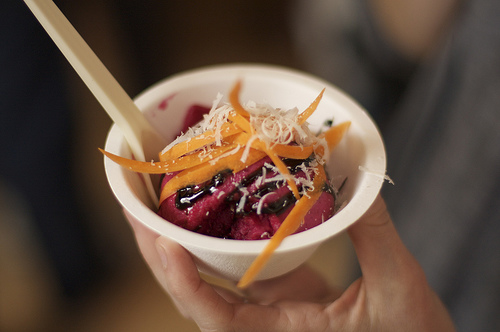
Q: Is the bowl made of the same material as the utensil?
A: Yes, both the bowl and the utensil are made of plastic.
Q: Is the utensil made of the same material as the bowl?
A: Yes, both the utensil and the bowl are made of plastic.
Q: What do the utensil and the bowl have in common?
A: The material, both the utensil and the bowl are plastic.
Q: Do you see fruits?
A: Yes, there is a fruit.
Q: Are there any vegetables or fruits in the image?
A: Yes, there is a fruit.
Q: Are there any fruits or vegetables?
A: Yes, there is a fruit.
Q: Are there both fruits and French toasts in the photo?
A: No, there is a fruit but no French toasts.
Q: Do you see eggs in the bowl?
A: No, there is a fruit in the bowl.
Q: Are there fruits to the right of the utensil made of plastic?
A: Yes, there is a fruit to the right of the utensil.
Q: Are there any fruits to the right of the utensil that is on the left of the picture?
A: Yes, there is a fruit to the right of the utensil.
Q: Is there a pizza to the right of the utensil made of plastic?
A: No, there is a fruit to the right of the utensil.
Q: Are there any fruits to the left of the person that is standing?
A: Yes, there is a fruit to the left of the person.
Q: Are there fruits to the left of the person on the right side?
A: Yes, there is a fruit to the left of the person.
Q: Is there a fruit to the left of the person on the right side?
A: Yes, there is a fruit to the left of the person.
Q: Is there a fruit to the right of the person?
A: No, the fruit is to the left of the person.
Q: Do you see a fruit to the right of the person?
A: No, the fruit is to the left of the person.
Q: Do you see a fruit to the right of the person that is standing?
A: No, the fruit is to the left of the person.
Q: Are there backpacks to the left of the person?
A: No, there is a fruit to the left of the person.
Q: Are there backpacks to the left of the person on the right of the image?
A: No, there is a fruit to the left of the person.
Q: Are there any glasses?
A: No, there are no glasses.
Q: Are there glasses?
A: No, there are no glasses.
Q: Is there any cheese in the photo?
A: Yes, there is cheese.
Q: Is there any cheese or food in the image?
A: Yes, there is cheese.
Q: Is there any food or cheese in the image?
A: Yes, there is cheese.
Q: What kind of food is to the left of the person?
A: The food is cheese.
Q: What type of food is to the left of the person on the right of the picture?
A: The food is cheese.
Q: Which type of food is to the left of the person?
A: The food is cheese.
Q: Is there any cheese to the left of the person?
A: Yes, there is cheese to the left of the person.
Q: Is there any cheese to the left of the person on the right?
A: Yes, there is cheese to the left of the person.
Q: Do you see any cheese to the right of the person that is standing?
A: No, the cheese is to the left of the person.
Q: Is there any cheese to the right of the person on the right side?
A: No, the cheese is to the left of the person.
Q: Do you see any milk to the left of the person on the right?
A: No, there is cheese to the left of the person.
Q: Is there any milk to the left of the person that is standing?
A: No, there is cheese to the left of the person.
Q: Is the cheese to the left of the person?
A: Yes, the cheese is to the left of the person.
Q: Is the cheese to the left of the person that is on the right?
A: Yes, the cheese is to the left of the person.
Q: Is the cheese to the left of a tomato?
A: No, the cheese is to the left of the person.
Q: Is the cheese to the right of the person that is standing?
A: No, the cheese is to the left of the person.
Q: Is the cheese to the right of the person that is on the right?
A: No, the cheese is to the left of the person.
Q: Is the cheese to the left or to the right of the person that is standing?
A: The cheese is to the left of the person.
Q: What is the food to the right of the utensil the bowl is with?
A: The food is cheese.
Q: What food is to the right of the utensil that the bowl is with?
A: The food is cheese.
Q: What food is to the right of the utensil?
A: The food is cheese.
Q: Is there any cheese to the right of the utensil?
A: Yes, there is cheese to the right of the utensil.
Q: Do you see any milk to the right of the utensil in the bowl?
A: No, there is cheese to the right of the utensil.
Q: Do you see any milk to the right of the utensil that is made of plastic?
A: No, there is cheese to the right of the utensil.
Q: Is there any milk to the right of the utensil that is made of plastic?
A: No, there is cheese to the right of the utensil.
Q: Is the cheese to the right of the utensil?
A: Yes, the cheese is to the right of the utensil.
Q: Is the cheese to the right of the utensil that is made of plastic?
A: Yes, the cheese is to the right of the utensil.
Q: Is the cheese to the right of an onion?
A: No, the cheese is to the right of the utensil.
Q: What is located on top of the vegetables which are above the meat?
A: The cheese is on top of the carrots.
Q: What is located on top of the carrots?
A: The cheese is on top of the carrots.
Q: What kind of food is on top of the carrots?
A: The food is cheese.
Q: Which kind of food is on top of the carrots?
A: The food is cheese.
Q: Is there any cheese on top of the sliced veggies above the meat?
A: Yes, there is cheese on top of the carrots.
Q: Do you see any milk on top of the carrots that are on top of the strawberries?
A: No, there is cheese on top of the carrots.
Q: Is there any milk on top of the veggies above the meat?
A: No, there is cheese on top of the carrots.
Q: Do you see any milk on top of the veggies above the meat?
A: No, there is cheese on top of the carrots.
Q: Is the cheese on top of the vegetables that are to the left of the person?
A: Yes, the cheese is on top of the carrots.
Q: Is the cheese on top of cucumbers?
A: No, the cheese is on top of the carrots.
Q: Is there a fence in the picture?
A: No, there are no fences.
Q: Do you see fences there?
A: No, there are no fences.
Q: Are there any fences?
A: No, there are no fences.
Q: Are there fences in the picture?
A: No, there are no fences.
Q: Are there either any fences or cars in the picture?
A: No, there are no fences or cars.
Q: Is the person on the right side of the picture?
A: Yes, the person is on the right of the image.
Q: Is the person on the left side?
A: No, the person is on the right of the image.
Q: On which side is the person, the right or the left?
A: The person is on the right of the image.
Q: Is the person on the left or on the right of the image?
A: The person is on the right of the image.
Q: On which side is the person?
A: The person is on the right of the image.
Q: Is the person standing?
A: Yes, the person is standing.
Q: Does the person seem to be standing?
A: Yes, the person is standing.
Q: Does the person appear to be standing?
A: Yes, the person is standing.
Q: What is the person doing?
A: The person is standing.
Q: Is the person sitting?
A: No, the person is standing.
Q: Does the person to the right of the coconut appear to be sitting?
A: No, the person is standing.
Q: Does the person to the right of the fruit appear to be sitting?
A: No, the person is standing.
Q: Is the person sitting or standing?
A: The person is standing.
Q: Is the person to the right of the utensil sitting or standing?
A: The person is standing.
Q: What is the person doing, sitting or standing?
A: The person is standing.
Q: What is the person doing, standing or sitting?
A: The person is standing.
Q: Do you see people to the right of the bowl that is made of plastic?
A: Yes, there is a person to the right of the bowl.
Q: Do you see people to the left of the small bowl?
A: No, the person is to the right of the bowl.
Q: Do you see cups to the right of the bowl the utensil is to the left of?
A: No, there is a person to the right of the bowl.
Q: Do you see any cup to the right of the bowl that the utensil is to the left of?
A: No, there is a person to the right of the bowl.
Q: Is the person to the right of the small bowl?
A: Yes, the person is to the right of the bowl.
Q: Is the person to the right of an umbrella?
A: No, the person is to the right of the bowl.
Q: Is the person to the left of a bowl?
A: No, the person is to the right of a bowl.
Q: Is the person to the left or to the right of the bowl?
A: The person is to the right of the bowl.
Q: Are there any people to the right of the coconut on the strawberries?
A: Yes, there is a person to the right of the coconut.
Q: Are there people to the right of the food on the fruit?
A: Yes, there is a person to the right of the coconut.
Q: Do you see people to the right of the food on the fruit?
A: Yes, there is a person to the right of the coconut.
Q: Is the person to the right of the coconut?
A: Yes, the person is to the right of the coconut.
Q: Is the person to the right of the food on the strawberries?
A: Yes, the person is to the right of the coconut.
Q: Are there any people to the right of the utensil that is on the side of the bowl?
A: Yes, there is a person to the right of the utensil.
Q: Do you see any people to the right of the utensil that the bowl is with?
A: Yes, there is a person to the right of the utensil.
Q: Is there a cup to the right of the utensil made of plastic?
A: No, there is a person to the right of the utensil.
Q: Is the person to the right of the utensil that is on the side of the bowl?
A: Yes, the person is to the right of the utensil.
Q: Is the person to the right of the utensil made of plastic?
A: Yes, the person is to the right of the utensil.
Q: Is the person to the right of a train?
A: No, the person is to the right of the utensil.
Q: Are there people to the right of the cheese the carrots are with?
A: Yes, there is a person to the right of the cheese.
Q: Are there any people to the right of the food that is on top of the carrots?
A: Yes, there is a person to the right of the cheese.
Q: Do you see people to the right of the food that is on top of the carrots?
A: Yes, there is a person to the right of the cheese.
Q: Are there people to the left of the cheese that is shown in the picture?
A: No, the person is to the right of the cheese.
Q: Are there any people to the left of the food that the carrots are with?
A: No, the person is to the right of the cheese.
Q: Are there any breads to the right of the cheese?
A: No, there is a person to the right of the cheese.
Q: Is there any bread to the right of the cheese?
A: No, there is a person to the right of the cheese.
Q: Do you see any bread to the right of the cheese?
A: No, there is a person to the right of the cheese.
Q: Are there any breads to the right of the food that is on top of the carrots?
A: No, there is a person to the right of the cheese.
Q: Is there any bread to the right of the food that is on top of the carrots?
A: No, there is a person to the right of the cheese.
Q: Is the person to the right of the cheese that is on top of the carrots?
A: Yes, the person is to the right of the cheese.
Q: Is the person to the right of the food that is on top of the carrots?
A: Yes, the person is to the right of the cheese.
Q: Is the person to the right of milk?
A: No, the person is to the right of the cheese.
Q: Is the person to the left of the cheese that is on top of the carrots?
A: No, the person is to the right of the cheese.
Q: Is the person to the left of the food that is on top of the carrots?
A: No, the person is to the right of the cheese.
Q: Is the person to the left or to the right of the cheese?
A: The person is to the right of the cheese.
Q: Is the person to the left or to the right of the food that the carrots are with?
A: The person is to the right of the cheese.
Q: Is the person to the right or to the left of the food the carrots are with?
A: The person is to the right of the cheese.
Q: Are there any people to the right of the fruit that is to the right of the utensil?
A: Yes, there is a person to the right of the fruit.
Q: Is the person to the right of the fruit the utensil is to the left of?
A: Yes, the person is to the right of the fruit.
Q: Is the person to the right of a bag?
A: No, the person is to the right of the fruit.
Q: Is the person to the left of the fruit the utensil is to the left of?
A: No, the person is to the right of the fruit.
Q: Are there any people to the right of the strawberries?
A: Yes, there is a person to the right of the strawberries.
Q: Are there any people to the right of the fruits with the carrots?
A: Yes, there is a person to the right of the strawberries.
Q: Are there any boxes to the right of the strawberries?
A: No, there is a person to the right of the strawberries.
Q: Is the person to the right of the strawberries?
A: Yes, the person is to the right of the strawberries.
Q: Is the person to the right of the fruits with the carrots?
A: Yes, the person is to the right of the strawberries.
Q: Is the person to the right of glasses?
A: No, the person is to the right of the strawberries.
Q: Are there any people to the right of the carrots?
A: Yes, there is a person to the right of the carrots.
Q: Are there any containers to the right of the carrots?
A: No, there is a person to the right of the carrots.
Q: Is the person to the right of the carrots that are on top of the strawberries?
A: Yes, the person is to the right of the carrots.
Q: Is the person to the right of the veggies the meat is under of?
A: Yes, the person is to the right of the carrots.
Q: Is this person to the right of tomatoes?
A: No, the person is to the right of the carrots.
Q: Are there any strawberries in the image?
A: Yes, there are strawberries.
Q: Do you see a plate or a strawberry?
A: Yes, there are strawberries.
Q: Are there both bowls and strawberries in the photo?
A: Yes, there are both strawberries and a bowl.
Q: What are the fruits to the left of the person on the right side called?
A: The fruits are strawberries.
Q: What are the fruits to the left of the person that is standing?
A: The fruits are strawberries.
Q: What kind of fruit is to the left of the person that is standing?
A: The fruits are strawberries.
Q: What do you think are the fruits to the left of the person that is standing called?
A: The fruits are strawberries.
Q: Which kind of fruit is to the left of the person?
A: The fruits are strawberries.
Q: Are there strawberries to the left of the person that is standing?
A: Yes, there are strawberries to the left of the person.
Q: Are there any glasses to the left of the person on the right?
A: No, there are strawberries to the left of the person.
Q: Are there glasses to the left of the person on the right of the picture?
A: No, there are strawberries to the left of the person.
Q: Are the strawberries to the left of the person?
A: Yes, the strawberries are to the left of the person.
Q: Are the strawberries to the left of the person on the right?
A: Yes, the strawberries are to the left of the person.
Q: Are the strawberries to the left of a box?
A: No, the strawberries are to the left of the person.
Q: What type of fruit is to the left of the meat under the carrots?
A: The fruits are strawberries.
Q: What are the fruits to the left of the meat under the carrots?
A: The fruits are strawberries.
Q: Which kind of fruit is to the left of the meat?
A: The fruits are strawberries.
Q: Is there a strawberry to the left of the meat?
A: Yes, there are strawberries to the left of the meat.